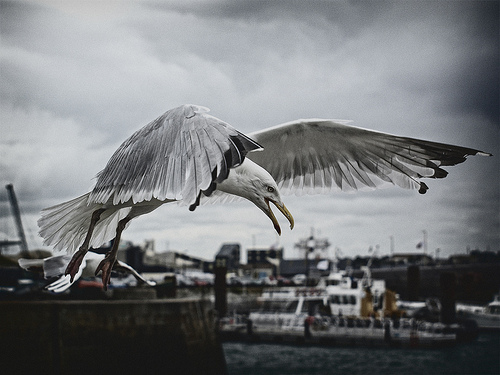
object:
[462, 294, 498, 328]
sail boat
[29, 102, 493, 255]
feathers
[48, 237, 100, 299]
feet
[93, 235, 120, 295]
foot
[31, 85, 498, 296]
seagull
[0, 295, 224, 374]
fence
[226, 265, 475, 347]
boat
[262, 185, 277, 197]
eye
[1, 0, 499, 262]
sky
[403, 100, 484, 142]
dark clouds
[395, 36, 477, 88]
dark clouds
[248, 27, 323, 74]
dark clouds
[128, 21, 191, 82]
dark clouds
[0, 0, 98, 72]
dark clouds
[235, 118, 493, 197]
left wing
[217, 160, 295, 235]
bird's head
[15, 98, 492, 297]
bird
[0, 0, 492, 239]
sky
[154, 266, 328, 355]
harbor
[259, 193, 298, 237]
beak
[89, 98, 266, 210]
right wing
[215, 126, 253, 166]
feather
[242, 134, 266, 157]
tip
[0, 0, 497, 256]
clouds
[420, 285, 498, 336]
ship